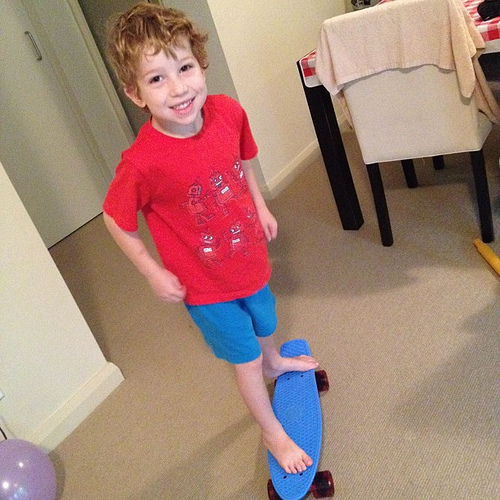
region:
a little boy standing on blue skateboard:
[86, 11, 351, 496]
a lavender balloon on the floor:
[8, 445, 52, 494]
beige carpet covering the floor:
[419, 324, 495, 438]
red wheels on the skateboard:
[319, 369, 341, 496]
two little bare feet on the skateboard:
[277, 347, 317, 480]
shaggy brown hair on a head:
[126, 23, 151, 50]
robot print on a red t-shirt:
[181, 165, 241, 220]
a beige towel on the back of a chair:
[343, 12, 450, 54]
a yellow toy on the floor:
[475, 237, 498, 281]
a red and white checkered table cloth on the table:
[484, 20, 498, 40]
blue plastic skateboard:
[254, 332, 341, 498]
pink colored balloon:
[1, 433, 59, 498]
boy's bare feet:
[262, 349, 322, 472]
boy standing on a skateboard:
[91, 5, 328, 480]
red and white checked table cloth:
[296, 1, 498, 78]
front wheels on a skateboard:
[261, 471, 343, 498]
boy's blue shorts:
[179, 274, 285, 368]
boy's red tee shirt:
[87, 89, 281, 309]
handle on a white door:
[21, 25, 51, 67]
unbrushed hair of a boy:
[101, 2, 211, 93]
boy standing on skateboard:
[78, 8, 359, 498]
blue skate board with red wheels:
[243, 326, 358, 498]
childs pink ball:
[0, 423, 67, 499]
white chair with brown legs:
[312, 6, 498, 248]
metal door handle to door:
[17, 20, 58, 79]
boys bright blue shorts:
[170, 264, 328, 384]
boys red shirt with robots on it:
[82, 103, 325, 303]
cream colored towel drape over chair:
[320, 2, 499, 144]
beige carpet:
[122, 318, 219, 465]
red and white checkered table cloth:
[297, 13, 482, 102]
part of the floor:
[385, 252, 434, 305]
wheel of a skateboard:
[314, 472, 332, 495]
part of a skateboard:
[285, 405, 315, 440]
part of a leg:
[266, 427, 303, 474]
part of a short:
[216, 321, 258, 356]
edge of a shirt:
[214, 291, 239, 311]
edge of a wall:
[78, 396, 104, 421]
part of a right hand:
[154, 280, 194, 322]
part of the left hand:
[253, 204, 278, 246]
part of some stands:
[349, 206, 413, 277]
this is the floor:
[366, 358, 466, 447]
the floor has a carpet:
[354, 350, 456, 450]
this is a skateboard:
[265, 340, 320, 494]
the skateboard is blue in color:
[278, 383, 315, 415]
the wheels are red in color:
[316, 476, 332, 493]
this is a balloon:
[5, 445, 45, 492]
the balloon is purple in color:
[5, 450, 38, 486]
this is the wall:
[230, 16, 278, 66]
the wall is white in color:
[228, 7, 256, 42]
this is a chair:
[320, 11, 491, 234]